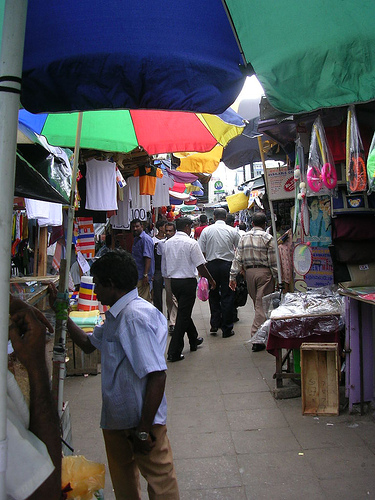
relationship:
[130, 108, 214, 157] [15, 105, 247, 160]
panel on top of umbrella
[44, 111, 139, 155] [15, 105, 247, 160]
panel on top of umbrella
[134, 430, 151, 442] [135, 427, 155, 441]
watch on top of wrist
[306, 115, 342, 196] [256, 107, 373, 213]
item on display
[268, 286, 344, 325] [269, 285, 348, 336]
table has plastic